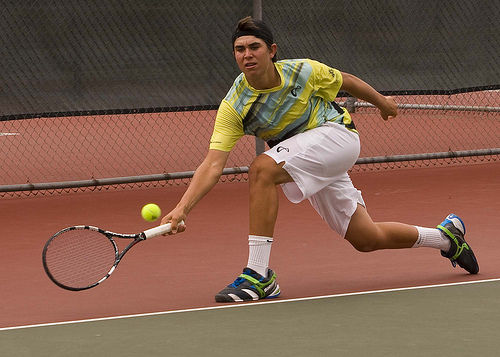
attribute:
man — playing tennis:
[158, 14, 490, 304]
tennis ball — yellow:
[135, 200, 167, 225]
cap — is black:
[230, 18, 274, 46]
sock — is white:
[243, 218, 286, 284]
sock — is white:
[407, 208, 470, 252]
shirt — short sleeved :
[204, 59, 394, 151]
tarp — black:
[2, 1, 497, 122]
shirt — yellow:
[206, 57, 355, 151]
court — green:
[1, 0, 499, 355]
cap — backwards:
[222, 24, 300, 65]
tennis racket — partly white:
[32, 212, 169, 296]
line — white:
[0, 278, 499, 331]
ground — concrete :
[338, 275, 428, 307]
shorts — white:
[259, 119, 369, 243]